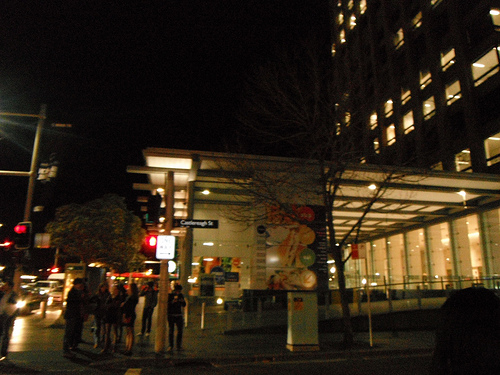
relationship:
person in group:
[122, 281, 141, 358] [60, 270, 141, 360]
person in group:
[109, 283, 126, 352] [60, 270, 141, 360]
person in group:
[92, 282, 113, 353] [60, 270, 141, 360]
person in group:
[58, 274, 86, 363] [60, 270, 141, 360]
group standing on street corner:
[60, 270, 141, 360] [3, 326, 163, 369]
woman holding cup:
[164, 283, 189, 354] [171, 293, 179, 304]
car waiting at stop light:
[10, 280, 44, 318] [12, 222, 27, 239]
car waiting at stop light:
[32, 278, 58, 300] [12, 222, 27, 239]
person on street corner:
[58, 274, 86, 363] [3, 326, 163, 369]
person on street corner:
[164, 283, 189, 354] [3, 326, 163, 369]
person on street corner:
[92, 282, 113, 353] [3, 326, 163, 369]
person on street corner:
[109, 283, 126, 352] [3, 326, 163, 369]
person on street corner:
[122, 281, 141, 358] [3, 326, 163, 369]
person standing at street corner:
[58, 274, 86, 363] [3, 326, 163, 369]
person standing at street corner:
[92, 282, 113, 353] [3, 326, 163, 369]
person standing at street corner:
[109, 283, 126, 352] [3, 326, 163, 369]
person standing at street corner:
[122, 281, 141, 358] [3, 326, 163, 369]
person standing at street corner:
[141, 278, 157, 334] [3, 326, 163, 369]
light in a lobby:
[464, 231, 483, 243] [332, 201, 499, 295]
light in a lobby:
[438, 233, 450, 249] [332, 201, 499, 295]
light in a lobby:
[416, 231, 424, 239] [332, 201, 499, 295]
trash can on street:
[35, 298, 49, 323] [1, 265, 74, 320]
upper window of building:
[332, 1, 341, 8] [310, 2, 499, 319]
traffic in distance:
[1, 256, 63, 314] [0, 255, 195, 319]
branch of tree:
[340, 158, 430, 250] [208, 29, 443, 348]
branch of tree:
[231, 173, 320, 236] [208, 29, 443, 348]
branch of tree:
[231, 112, 298, 146] [208, 29, 443, 348]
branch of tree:
[304, 42, 328, 128] [208, 29, 443, 348]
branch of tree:
[279, 52, 312, 123] [208, 29, 443, 348]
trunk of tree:
[321, 208, 358, 348] [208, 29, 443, 348]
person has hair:
[109, 283, 126, 352] [116, 280, 126, 297]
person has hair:
[122, 281, 141, 358] [132, 282, 140, 307]